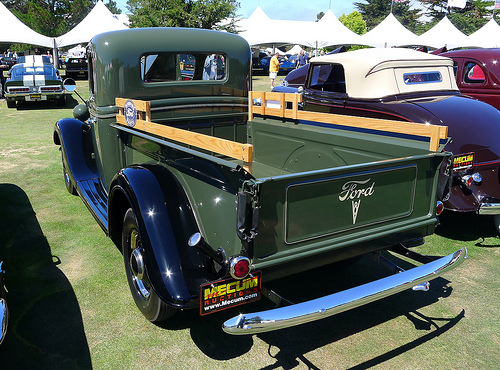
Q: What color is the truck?
A: Green.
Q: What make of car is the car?
A: A Ford.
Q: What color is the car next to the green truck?
A: Purple and white.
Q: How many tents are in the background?
A: Seven.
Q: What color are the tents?
A: White.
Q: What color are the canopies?
A: White.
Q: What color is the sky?
A: Blue.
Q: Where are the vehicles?
A: In a field.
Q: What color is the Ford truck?
A: Green.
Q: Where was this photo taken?
A: At an antique car show.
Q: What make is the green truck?
A: Ford.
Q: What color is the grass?
A: Green.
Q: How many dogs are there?
A: None.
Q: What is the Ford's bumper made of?
A: Metal.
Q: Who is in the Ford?
A: Nobody.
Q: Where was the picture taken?
A: At a car show.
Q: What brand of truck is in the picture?
A: Ford.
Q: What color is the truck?
A: Green.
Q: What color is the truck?
A: Green.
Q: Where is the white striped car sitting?
A: In front of the truck.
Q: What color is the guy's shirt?
A: Yellow.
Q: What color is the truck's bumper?
A: Chrome.